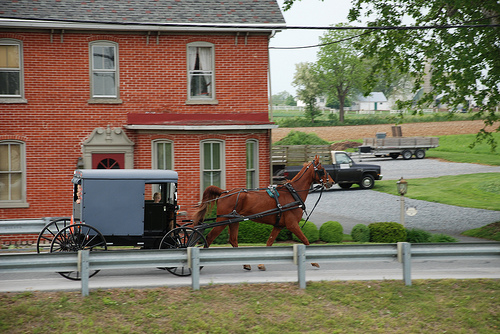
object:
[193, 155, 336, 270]
horse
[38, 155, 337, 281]
buggy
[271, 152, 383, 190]
truck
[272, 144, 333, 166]
wood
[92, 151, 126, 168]
door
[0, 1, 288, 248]
building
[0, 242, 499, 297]
rail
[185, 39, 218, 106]
window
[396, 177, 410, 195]
light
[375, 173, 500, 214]
grass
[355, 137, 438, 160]
trailer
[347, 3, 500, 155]
tree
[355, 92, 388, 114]
house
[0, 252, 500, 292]
road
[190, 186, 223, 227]
tail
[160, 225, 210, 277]
wheel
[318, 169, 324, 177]
blinder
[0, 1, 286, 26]
roof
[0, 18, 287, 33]
gutter